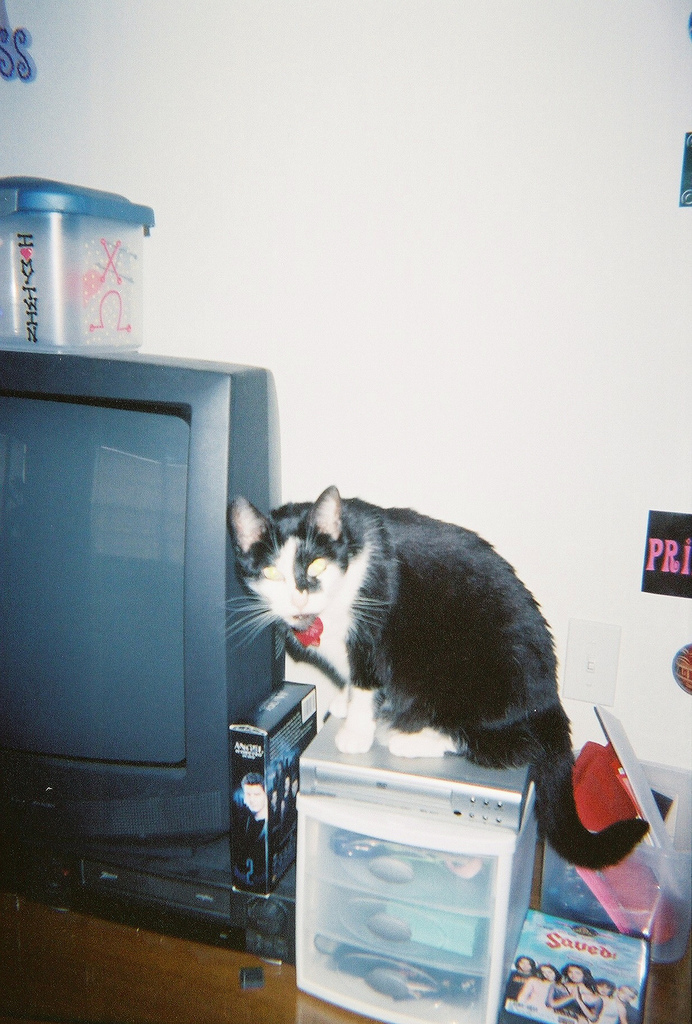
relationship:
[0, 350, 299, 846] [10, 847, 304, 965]
television on top of vcr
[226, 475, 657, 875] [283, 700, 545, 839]
cat on top of dvd player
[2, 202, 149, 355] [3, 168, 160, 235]
container with lid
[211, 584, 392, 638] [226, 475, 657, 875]
whiskers on cat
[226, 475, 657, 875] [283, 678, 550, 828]
cat sitting on dvd player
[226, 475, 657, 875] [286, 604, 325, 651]
cat with tag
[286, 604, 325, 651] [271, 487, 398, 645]
tag on neck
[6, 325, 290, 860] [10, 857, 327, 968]
television sitting on a vcr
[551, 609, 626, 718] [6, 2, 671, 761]
jack on wall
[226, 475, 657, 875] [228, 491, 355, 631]
cat with face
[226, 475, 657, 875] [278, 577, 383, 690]
cat with chest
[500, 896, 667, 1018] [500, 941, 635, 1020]
dvd cover displaying people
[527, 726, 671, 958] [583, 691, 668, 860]
container with lid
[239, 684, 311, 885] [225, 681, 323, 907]
cassette tape in box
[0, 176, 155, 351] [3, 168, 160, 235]
container with lid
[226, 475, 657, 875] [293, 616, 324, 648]
cat with tag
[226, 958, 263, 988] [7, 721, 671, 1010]
dust in floor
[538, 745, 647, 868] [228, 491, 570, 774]
tail on cat